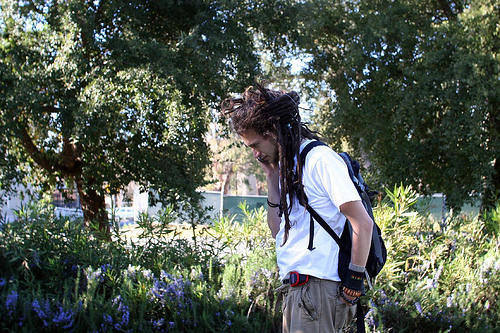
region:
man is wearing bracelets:
[338, 256, 370, 299]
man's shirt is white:
[266, 138, 362, 279]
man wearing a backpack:
[226, 83, 387, 330]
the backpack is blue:
[325, 150, 393, 276]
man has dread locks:
[223, 84, 320, 253]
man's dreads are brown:
[219, 86, 328, 253]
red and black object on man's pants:
[275, 267, 312, 291]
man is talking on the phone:
[223, 74, 398, 331]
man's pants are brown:
[269, 279, 354, 331]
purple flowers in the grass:
[3, 251, 498, 327]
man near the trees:
[217, 75, 378, 315]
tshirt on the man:
[292, 166, 372, 219]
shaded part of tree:
[34, 108, 165, 148]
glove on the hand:
[330, 262, 368, 309]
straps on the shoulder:
[290, 129, 320, 223]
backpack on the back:
[365, 235, 384, 275]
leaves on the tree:
[417, 73, 463, 161]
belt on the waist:
[284, 266, 314, 287]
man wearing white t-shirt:
[231, 88, 364, 288]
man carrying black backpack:
[295, 137, 387, 298]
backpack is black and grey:
[295, 135, 387, 290]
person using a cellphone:
[225, 81, 376, 327]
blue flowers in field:
[5, 260, 198, 330]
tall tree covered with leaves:
[0, 1, 206, 233]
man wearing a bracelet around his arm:
[257, 160, 287, 240]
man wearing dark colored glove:
[336, 255, 366, 303]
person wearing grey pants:
[225, 82, 385, 331]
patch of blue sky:
[293, 56, 301, 68]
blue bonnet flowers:
[119, 304, 132, 324]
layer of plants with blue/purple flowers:
[0, 270, 265, 330]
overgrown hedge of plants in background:
[6, 201, 237, 251]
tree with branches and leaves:
[0, 0, 208, 237]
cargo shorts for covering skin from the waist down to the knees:
[286, 283, 341, 332]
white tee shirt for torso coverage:
[272, 144, 340, 284]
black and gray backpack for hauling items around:
[302, 139, 385, 274]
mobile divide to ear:
[258, 155, 270, 167]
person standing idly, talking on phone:
[218, 80, 389, 330]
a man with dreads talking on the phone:
[221, 93, 385, 327]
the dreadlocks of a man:
[242, 93, 306, 160]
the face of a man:
[240, 131, 270, 165]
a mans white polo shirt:
[277, 163, 354, 271]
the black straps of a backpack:
[278, 151, 335, 233]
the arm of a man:
[251, 171, 288, 229]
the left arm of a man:
[315, 166, 373, 277]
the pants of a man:
[264, 269, 341, 331]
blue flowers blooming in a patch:
[108, 269, 188, 320]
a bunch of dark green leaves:
[62, 71, 166, 171]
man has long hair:
[234, 83, 323, 242]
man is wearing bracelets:
[341, 253, 364, 314]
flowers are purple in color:
[19, 251, 202, 325]